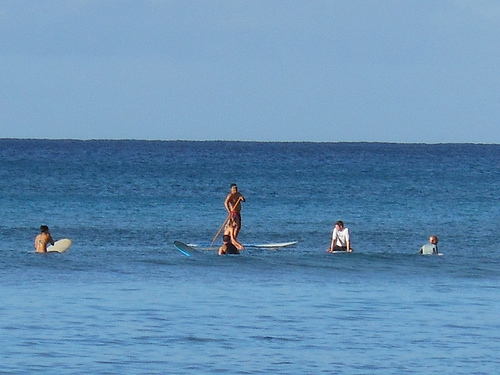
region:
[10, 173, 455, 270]
several people on the water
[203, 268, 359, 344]
calm blue water of the ocean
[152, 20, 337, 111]
clear blue skies over the ocean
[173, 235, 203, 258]
a black and blue surfboard in the water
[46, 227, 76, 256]
a white surfboard in the water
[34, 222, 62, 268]
a woman sitting on a white surfboard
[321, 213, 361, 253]
a man wearing a white shirt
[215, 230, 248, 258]
a man wearing a black shirt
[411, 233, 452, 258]
a person wearing a blue shirt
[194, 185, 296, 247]
a man standing on a white surfboard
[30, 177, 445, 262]
Five people are out in the ocean.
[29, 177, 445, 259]
Five people are out in the water.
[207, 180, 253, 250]
A man is holding a paddle.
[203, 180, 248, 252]
A man is steering with a paddle.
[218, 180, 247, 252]
A man is standing on a surfboard.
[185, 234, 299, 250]
The color of a surfboard is white.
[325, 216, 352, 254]
A person is looking to the left.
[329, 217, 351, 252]
A person is wearing a white shirt.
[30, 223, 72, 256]
A female is in the water.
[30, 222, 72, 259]
A female is on a surfboard.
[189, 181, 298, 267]
A person is paddling on a surfboard.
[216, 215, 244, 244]
A woman is sitting in front of a man.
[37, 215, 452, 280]
A group of people are waiting for a wave.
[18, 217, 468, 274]
A group of people are sitting on a surfboard.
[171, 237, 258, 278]
A man is sitting on a blue surfboard.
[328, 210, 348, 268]
A man is wearing a white t-shirt.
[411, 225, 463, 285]
A man is wearing a blue t-shirt.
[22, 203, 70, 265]
A woman is wearing a bikini top.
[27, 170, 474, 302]
A group of people are floating on the ocean.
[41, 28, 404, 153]
The sky is displaying no clouds.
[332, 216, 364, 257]
A person in a white shirt.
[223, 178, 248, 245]
A person who is standing up.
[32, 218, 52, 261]
A person with a hand to their face.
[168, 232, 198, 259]
A partially visible blue sport board.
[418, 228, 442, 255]
A bald person partially visible.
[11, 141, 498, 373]
An area of water.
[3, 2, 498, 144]
An area of blue sky.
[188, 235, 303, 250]
An almost fully visible white board.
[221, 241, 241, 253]
A black shirt.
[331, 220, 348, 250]
A white shirt being worn by a man.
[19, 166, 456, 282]
people in the ocean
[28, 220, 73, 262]
person holding a surfboard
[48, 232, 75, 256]
surfboard is color white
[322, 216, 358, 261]
man wearing a white shirt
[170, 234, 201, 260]
surfboard is color blue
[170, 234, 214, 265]
half of surfboard is in the water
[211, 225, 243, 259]
surfer wears a black top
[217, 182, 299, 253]
a surfer stand on surfboard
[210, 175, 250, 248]
surfer holding a row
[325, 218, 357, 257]
man wears white top